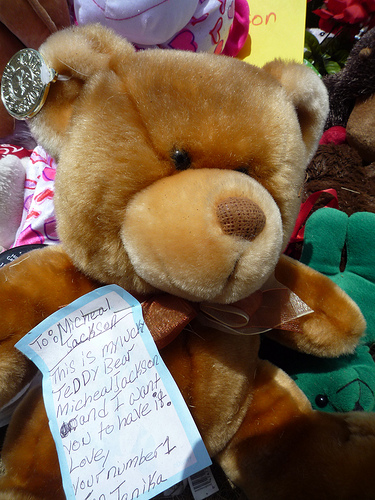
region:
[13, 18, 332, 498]
brown stuffed teddy bear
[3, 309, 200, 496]
hand written note in ink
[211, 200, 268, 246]
brown nose on teddy bear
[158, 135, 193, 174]
eye on teddy bear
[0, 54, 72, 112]
gold coin in teddy bear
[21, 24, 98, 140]
ear of teddy bear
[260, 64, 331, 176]
ear of teddy bear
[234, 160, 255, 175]
eye of teddy bear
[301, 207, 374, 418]
green teddy bear upside down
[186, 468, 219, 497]
bar code of stuffed animal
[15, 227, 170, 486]
the teddy bear has note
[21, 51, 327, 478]
the teddy bear is brown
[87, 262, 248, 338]
the teddy bear is wearing a ribbon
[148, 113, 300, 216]
the eyes are black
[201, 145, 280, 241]
the nose is brown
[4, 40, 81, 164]
the tag is silver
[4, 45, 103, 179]
the teddy bear has a tag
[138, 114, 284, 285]
the teddy bear is brown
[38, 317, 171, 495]
the note is blue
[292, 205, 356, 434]
the teddy bear is green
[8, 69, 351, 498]
a fuzzy brown teddy bear with a hand-written note attached to it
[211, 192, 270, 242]
a brown woven nose of the teddy bear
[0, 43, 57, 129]
a shiny gold medallion attached to the bear's ear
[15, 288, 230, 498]
a hand-written note on the teddy bear addressed to Michael Jackson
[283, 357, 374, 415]
the face of a smaller green teddy bear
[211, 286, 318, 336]
a brown ribbon tied in a bow around the bear's neck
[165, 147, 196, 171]
a small black eye on the teddy bear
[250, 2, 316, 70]
a small part of a yellow hand-written note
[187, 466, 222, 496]
a white and black tag with a UPC code on it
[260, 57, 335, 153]
a brown furry ear of the teddy bear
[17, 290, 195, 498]
a note to Michael Jackson from a fan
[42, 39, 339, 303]
a teddy bear to Michael Jackson from a fan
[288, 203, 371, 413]
a green teddy bear in the background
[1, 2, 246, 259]
a purple stuffed toy behind the bear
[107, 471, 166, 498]
the fan who wrote the note is named Tanika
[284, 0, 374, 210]
stuffed toys and flowers in the background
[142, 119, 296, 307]
the bear has black eyes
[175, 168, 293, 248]
the bear has a brown nose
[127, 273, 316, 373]
the bear is wearning a tie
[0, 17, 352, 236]
some kind of coin is attached to the bear's ear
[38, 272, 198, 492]
handwritten note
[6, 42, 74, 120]
gold tag on teddy bears ear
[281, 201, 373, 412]
little green upside down teddy bear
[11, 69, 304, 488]
large brown teddy bear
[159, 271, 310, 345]
brown and pink bow around teddy bears neck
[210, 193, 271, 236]
brown nose of teddy bear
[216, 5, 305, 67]
yellow paper with red lettering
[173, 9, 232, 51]
red and pink hearts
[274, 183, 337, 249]
thin red ribbon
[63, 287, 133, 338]
note stapled to teddy bear